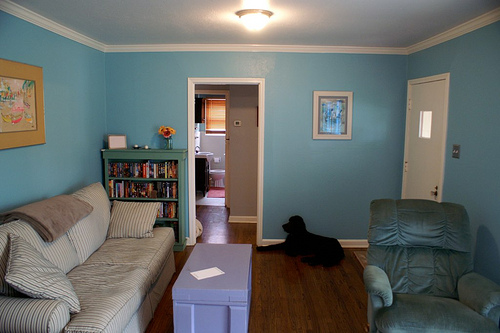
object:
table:
[170, 241, 255, 332]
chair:
[361, 197, 497, 332]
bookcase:
[100, 146, 189, 253]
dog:
[253, 213, 347, 270]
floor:
[144, 218, 370, 333]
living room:
[0, 0, 499, 333]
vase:
[163, 136, 172, 150]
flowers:
[163, 130, 172, 137]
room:
[0, 0, 499, 333]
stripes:
[136, 203, 146, 239]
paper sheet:
[189, 266, 226, 280]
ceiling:
[12, 0, 499, 49]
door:
[399, 70, 453, 201]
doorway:
[194, 83, 257, 243]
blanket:
[0, 193, 94, 244]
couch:
[0, 183, 177, 333]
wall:
[0, 0, 499, 289]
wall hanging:
[312, 90, 353, 140]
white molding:
[0, 0, 500, 55]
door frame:
[185, 75, 266, 247]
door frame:
[400, 72, 451, 203]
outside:
[206, 98, 227, 131]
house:
[0, 0, 499, 333]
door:
[193, 83, 259, 247]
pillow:
[4, 232, 82, 313]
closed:
[400, 72, 452, 203]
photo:
[0, 0, 498, 330]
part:
[177, 130, 192, 256]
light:
[232, 8, 271, 32]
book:
[112, 162, 117, 177]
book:
[153, 163, 157, 178]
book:
[166, 182, 170, 199]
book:
[133, 162, 140, 178]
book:
[156, 181, 162, 199]